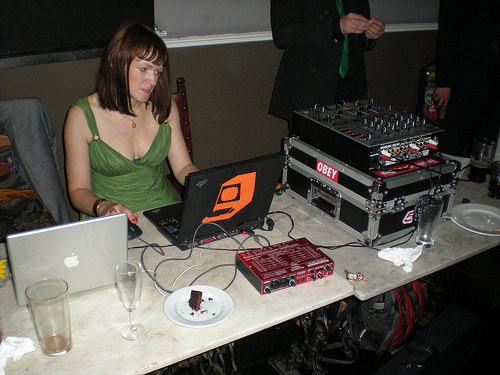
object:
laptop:
[141, 152, 289, 253]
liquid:
[43, 335, 69, 353]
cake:
[188, 290, 203, 312]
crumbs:
[480, 225, 485, 228]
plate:
[442, 203, 499, 238]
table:
[0, 184, 493, 375]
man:
[266, 1, 388, 145]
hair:
[94, 23, 171, 125]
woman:
[60, 24, 203, 232]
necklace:
[116, 103, 144, 130]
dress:
[76, 98, 180, 220]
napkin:
[377, 245, 425, 274]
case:
[278, 131, 464, 249]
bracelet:
[92, 197, 107, 217]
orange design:
[200, 171, 257, 224]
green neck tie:
[336, 0, 350, 79]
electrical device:
[283, 93, 446, 176]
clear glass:
[23, 277, 76, 360]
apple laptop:
[4, 211, 129, 307]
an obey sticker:
[316, 160, 338, 184]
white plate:
[163, 284, 235, 328]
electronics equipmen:
[233, 236, 336, 297]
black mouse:
[127, 218, 143, 240]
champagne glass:
[112, 259, 150, 343]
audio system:
[282, 95, 466, 246]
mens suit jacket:
[2, 96, 75, 228]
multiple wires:
[318, 242, 369, 251]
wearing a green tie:
[335, 1, 353, 79]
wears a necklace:
[116, 103, 143, 129]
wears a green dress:
[54, 93, 181, 225]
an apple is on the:
[63, 252, 80, 269]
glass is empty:
[414, 194, 444, 248]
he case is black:
[360, 318, 477, 375]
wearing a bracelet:
[89, 197, 109, 218]